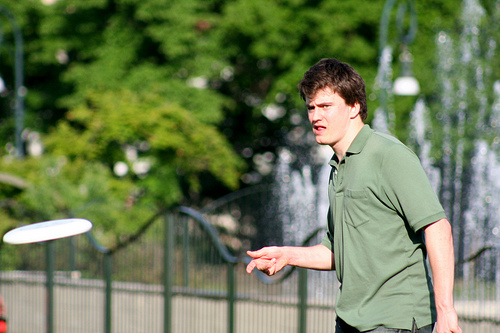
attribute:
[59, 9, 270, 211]
trees — green, leafy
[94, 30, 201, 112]
background — blurred